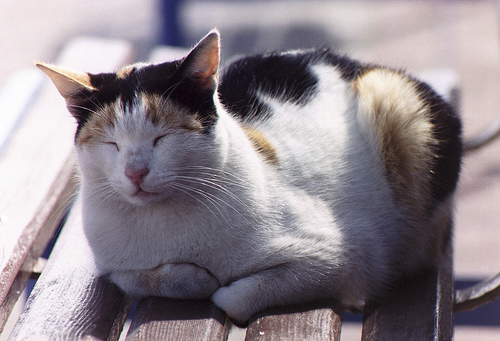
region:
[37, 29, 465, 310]
Three colored cat on bench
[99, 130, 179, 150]
Closed eyes in cat's head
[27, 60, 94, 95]
Light brown cat ear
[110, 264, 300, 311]
Cat's front paws tucked under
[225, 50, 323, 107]
Black fur on cat's back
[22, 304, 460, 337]
Wooden slats on bench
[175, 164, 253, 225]
White whiskers on cat's face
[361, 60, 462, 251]
Curve of cat's back leg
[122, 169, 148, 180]
Pink nose on cat's face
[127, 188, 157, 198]
Closed mouth on cat's face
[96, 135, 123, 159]
the white eye of a cat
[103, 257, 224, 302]
the white paw of a cat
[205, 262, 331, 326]
the white paw of a cat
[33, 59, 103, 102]
the brown ear of a cat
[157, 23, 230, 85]
the brown ear of a cat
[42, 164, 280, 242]
the white whiskers of a cat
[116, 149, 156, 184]
the pink nose of a cat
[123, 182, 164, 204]
the closed mouth of a cat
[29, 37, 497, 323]
a white cat with black and brown fur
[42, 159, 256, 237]
a spotted cat's whiskers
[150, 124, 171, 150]
a white cat's eye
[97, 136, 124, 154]
a white cat's eye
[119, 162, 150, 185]
a cat's pink nose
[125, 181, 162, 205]
a cat's closed mouth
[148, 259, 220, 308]
a cat's white paw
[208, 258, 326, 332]
a cat's white paw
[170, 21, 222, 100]
a cat's brown ear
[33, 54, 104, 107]
a cat's brown ear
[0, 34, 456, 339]
a cat on a wooden bench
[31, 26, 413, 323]
the cat is sleeping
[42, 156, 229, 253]
the cat has whiskers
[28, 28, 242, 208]
Head of calico cat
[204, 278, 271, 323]
Paw of calico cat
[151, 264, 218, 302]
Paw of calico cat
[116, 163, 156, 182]
Nose of calico cat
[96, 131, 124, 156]
Eye of calico cat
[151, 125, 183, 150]
Eye of calico at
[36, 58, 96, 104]
Ear of calico cat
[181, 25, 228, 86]
Ear of calico cat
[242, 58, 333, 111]
Back of calico cat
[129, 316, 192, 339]
Part of brown wooden bench